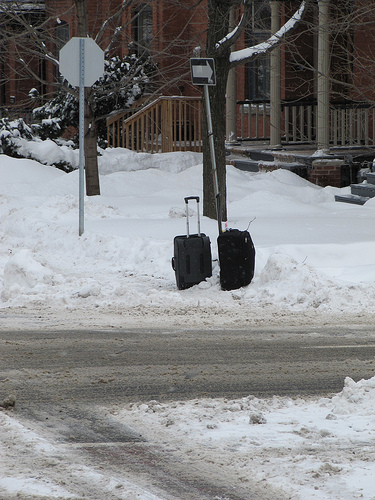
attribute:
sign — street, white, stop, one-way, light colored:
[62, 34, 220, 92]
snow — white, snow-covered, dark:
[16, 147, 366, 322]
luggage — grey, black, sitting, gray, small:
[171, 179, 256, 296]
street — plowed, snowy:
[6, 319, 373, 442]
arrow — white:
[189, 61, 212, 84]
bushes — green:
[8, 11, 362, 151]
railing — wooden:
[105, 87, 375, 153]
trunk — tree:
[80, 107, 104, 198]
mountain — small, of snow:
[241, 190, 298, 211]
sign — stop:
[54, 32, 110, 235]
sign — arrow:
[180, 55, 216, 85]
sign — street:
[181, 51, 234, 233]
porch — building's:
[116, 83, 361, 167]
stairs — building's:
[339, 160, 372, 212]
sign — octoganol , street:
[56, 33, 108, 87]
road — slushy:
[13, 282, 369, 411]